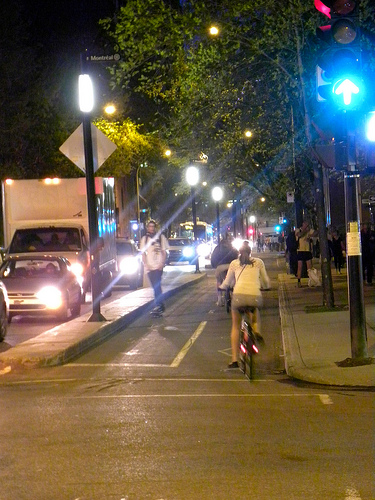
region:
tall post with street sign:
[66, 39, 165, 329]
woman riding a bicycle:
[210, 236, 282, 397]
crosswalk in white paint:
[1, 350, 355, 412]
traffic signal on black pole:
[305, 3, 374, 381]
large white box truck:
[3, 168, 126, 309]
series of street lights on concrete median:
[1, 43, 268, 374]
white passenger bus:
[175, 214, 222, 265]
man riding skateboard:
[129, 207, 181, 325]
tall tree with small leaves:
[94, 6, 337, 308]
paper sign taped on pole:
[334, 177, 369, 299]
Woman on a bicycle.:
[221, 241, 268, 378]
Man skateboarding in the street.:
[126, 230, 177, 317]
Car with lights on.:
[1, 270, 66, 313]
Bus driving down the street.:
[181, 217, 214, 262]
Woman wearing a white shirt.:
[225, 255, 276, 291]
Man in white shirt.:
[138, 232, 170, 271]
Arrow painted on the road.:
[124, 328, 149, 367]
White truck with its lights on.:
[20, 231, 117, 267]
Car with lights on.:
[113, 237, 143, 284]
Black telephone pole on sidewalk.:
[344, 232, 366, 355]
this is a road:
[39, 379, 245, 487]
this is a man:
[140, 222, 171, 309]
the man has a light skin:
[148, 227, 151, 230]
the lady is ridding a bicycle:
[226, 249, 264, 373]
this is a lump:
[78, 72, 97, 114]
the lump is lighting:
[79, 78, 92, 106]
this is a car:
[11, 258, 71, 309]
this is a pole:
[313, 169, 338, 309]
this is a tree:
[189, 10, 309, 173]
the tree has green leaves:
[179, 66, 210, 91]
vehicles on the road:
[4, 168, 221, 374]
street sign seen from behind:
[58, 61, 123, 320]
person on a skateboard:
[136, 211, 175, 324]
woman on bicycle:
[218, 236, 274, 379]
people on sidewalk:
[272, 213, 351, 303]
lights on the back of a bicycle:
[225, 336, 266, 362]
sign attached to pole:
[338, 193, 370, 272]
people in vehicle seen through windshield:
[9, 226, 79, 254]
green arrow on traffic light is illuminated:
[312, 5, 369, 111]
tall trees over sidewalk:
[97, 2, 342, 312]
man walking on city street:
[124, 213, 179, 328]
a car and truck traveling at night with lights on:
[0, 173, 103, 342]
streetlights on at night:
[168, 155, 238, 236]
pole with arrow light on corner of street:
[312, 39, 373, 369]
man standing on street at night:
[288, 213, 336, 306]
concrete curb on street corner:
[1, 320, 80, 375]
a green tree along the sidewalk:
[127, 13, 337, 193]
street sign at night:
[76, 48, 130, 67]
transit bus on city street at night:
[172, 215, 219, 243]